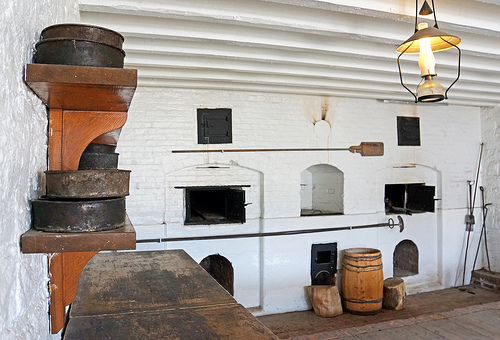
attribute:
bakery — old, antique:
[0, 2, 499, 338]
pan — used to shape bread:
[46, 168, 132, 199]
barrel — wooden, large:
[341, 247, 384, 314]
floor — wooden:
[251, 281, 499, 339]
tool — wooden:
[171, 142, 385, 157]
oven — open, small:
[187, 187, 244, 225]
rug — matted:
[285, 299, 499, 339]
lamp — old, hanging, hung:
[394, 2, 462, 103]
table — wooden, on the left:
[61, 248, 277, 338]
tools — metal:
[459, 141, 494, 296]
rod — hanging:
[126, 214, 403, 244]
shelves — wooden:
[22, 61, 138, 333]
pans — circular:
[26, 25, 132, 234]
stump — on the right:
[383, 276, 408, 309]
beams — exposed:
[78, 0, 499, 108]